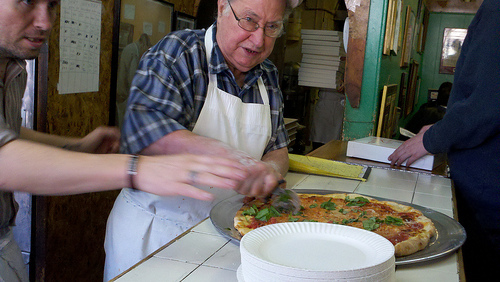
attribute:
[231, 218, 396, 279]
white plates — bunch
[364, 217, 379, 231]
leaf — green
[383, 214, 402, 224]
leaf — green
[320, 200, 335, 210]
leaf — green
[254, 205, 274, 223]
leaf — green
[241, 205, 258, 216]
leaf — green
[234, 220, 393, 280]
plates — white , bunch, stacked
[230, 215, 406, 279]
plates — white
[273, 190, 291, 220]
vegetable — green, leaf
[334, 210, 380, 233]
leaf — green